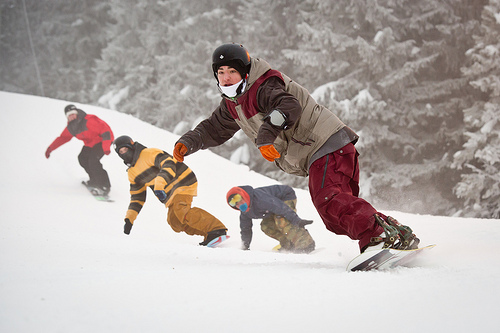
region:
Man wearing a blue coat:
[220, 174, 317, 263]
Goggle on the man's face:
[215, 183, 247, 208]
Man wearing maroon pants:
[175, 47, 436, 280]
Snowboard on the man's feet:
[344, 221, 437, 281]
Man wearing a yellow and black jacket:
[99, 134, 230, 250]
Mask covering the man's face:
[111, 141, 138, 167]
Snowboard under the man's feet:
[195, 230, 237, 254]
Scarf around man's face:
[214, 76, 244, 102]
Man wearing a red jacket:
[34, 96, 122, 203]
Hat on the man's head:
[60, 101, 78, 116]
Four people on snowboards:
[43, 40, 440, 273]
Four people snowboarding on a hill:
[40, 40, 436, 273]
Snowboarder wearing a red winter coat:
[42, 103, 116, 203]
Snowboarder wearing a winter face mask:
[111, 134, 230, 250]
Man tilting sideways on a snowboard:
[172, 40, 435, 275]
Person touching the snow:
[221, 181, 322, 256]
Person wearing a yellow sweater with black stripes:
[110, 132, 230, 249]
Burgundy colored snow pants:
[305, 134, 390, 253]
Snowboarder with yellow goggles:
[226, 180, 317, 257]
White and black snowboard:
[345, 242, 439, 272]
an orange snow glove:
[255, 145, 279, 160]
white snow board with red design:
[203, 235, 229, 250]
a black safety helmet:
[211, 42, 250, 69]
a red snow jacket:
[42, 116, 113, 153]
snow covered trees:
[309, 3, 496, 211]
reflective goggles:
[228, 194, 243, 204]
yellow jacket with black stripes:
[120, 150, 197, 220]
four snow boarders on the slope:
[42, 42, 425, 268]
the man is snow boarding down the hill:
[175, 39, 433, 268]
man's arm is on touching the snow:
[238, 209, 255, 250]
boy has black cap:
[208, 36, 258, 94]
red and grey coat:
[212, 80, 336, 175]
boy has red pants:
[276, 129, 368, 238]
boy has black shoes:
[365, 236, 432, 278]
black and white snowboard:
[355, 238, 426, 288]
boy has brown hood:
[106, 134, 147, 167]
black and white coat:
[129, 148, 202, 213]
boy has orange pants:
[169, 188, 225, 237]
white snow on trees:
[263, 29, 491, 221]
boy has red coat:
[60, 109, 111, 161]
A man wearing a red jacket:
[34, 109, 117, 164]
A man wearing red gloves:
[40, 144, 55, 164]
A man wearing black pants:
[72, 139, 115, 199]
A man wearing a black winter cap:
[107, 132, 137, 163]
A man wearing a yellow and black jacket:
[106, 151, 206, 227]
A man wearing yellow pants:
[150, 189, 232, 240]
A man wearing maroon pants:
[290, 141, 418, 253]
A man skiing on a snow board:
[322, 200, 452, 287]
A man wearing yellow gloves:
[169, 133, 286, 168]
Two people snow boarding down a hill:
[32, 94, 234, 253]